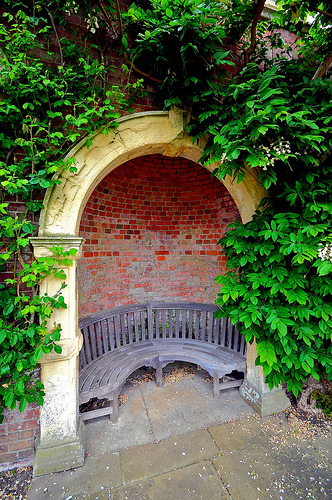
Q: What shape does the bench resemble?
A: A semicircle.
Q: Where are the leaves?
A: Around the walls.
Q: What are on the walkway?
A: Flower petals.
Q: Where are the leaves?
A: On the wall.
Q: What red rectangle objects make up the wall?
A: Bricks.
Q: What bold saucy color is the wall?
A: Red.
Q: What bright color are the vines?
A: Green.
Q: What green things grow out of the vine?
A: Leaves.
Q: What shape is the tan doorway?
A: Arched.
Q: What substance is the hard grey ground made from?
A: Concrete.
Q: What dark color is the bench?
A: Black.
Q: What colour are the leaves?
A: Green.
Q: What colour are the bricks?
A: Red.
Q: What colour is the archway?
A: Gold.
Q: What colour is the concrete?
A: Gray.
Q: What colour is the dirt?
A: Brown.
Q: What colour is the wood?
A: Black.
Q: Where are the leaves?
A: On the wall.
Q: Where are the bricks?
A: In the wall.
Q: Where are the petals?
A: On the ground.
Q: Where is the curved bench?
A: In the nook.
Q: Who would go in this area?
A: People wanting to sit on the bench.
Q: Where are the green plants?
A: Around the archway.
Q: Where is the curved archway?
A: Over the wooden bench.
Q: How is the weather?
A: Clear and sunny.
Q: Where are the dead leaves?
A: On the ground.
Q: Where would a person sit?
A: On the curved bench.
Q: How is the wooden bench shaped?
A: Like a half-circle.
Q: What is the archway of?
A: White pillar.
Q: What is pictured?
A: An alcove.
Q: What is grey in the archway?
A: A bench.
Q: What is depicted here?
A: An archway.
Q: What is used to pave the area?
A: Stone.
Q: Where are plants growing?
A: On the outside wall of archway.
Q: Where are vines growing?
A: Up the wall.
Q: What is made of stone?
A: The white pillar of archway.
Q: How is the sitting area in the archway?
A: Unique.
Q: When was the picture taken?
A: Daytime.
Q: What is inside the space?
A: A bench.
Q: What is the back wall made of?
A: Brick.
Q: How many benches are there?
A: One.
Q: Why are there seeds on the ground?
A: From the trees.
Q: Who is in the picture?
A: Nobody.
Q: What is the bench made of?
A: Wood.